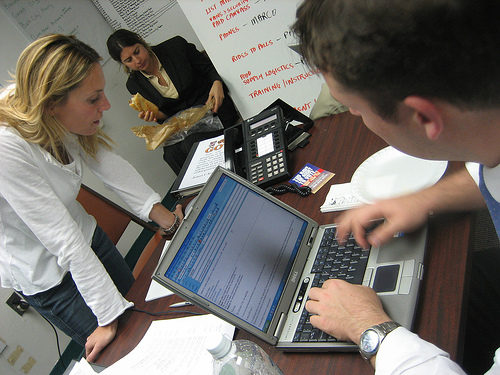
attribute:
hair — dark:
[103, 25, 146, 58]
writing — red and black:
[221, 8, 353, 133]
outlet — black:
[6, 291, 66, 373]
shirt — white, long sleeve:
[4, 89, 133, 361]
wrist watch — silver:
[342, 308, 415, 350]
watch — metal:
[336, 299, 410, 371]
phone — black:
[212, 94, 317, 209]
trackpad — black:
[372, 264, 399, 290]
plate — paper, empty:
[348, 141, 450, 205]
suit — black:
[122, 40, 217, 162]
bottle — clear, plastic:
[202, 333, 284, 374]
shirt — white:
[1, 122, 168, 324]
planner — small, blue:
[283, 158, 364, 207]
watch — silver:
[337, 328, 417, 340]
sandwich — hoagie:
[123, 86, 163, 124]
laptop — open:
[152, 165, 431, 363]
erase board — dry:
[181, 6, 326, 121]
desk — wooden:
[231, 72, 496, 250]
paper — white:
[108, 277, 205, 370]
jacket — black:
[124, 39, 234, 141]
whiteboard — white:
[208, 64, 246, 90]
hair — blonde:
[1, 30, 104, 163]